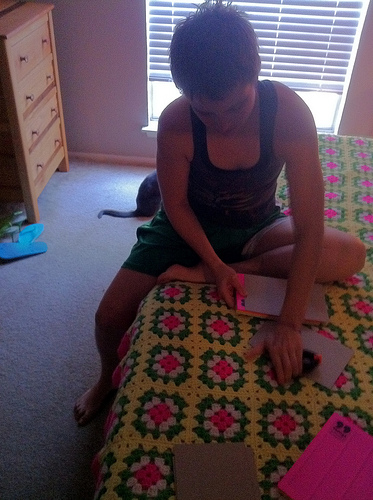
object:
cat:
[95, 169, 161, 221]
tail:
[96, 204, 138, 219]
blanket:
[89, 126, 372, 499]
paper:
[274, 408, 373, 499]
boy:
[71, 0, 365, 428]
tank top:
[156, 77, 281, 222]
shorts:
[118, 203, 289, 277]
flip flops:
[0, 242, 49, 263]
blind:
[145, 0, 365, 95]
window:
[140, 1, 367, 141]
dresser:
[0, 2, 70, 226]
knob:
[40, 37, 48, 46]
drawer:
[8, 18, 55, 86]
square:
[135, 342, 196, 390]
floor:
[0, 155, 164, 499]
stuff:
[169, 356, 277, 431]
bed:
[91, 134, 371, 499]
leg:
[93, 206, 179, 391]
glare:
[146, 4, 359, 136]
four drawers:
[7, 21, 65, 188]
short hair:
[167, 0, 261, 98]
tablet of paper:
[234, 253, 327, 326]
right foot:
[70, 375, 122, 429]